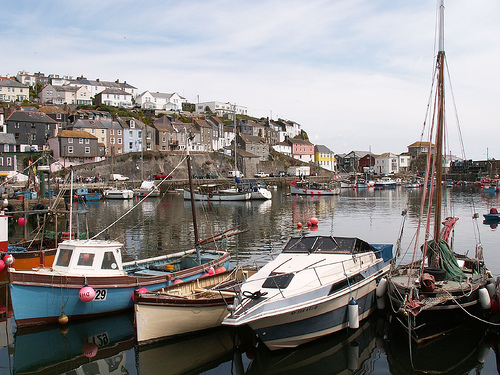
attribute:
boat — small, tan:
[130, 285, 234, 335]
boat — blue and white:
[219, 232, 398, 366]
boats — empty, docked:
[5, 160, 487, 355]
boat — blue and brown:
[25, 188, 217, 348]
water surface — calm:
[10, 186, 498, 283]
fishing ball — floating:
[307, 216, 317, 227]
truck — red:
[150, 169, 177, 180]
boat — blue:
[0, 230, 226, 341]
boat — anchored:
[197, 227, 425, 352]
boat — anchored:
[110, 221, 268, 351]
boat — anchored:
[0, 210, 252, 326]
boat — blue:
[385, 215, 489, 367]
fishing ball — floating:
[291, 209, 338, 239]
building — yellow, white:
[308, 140, 341, 180]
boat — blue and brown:
[9, 235, 234, 326]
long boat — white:
[181, 186, 249, 201]